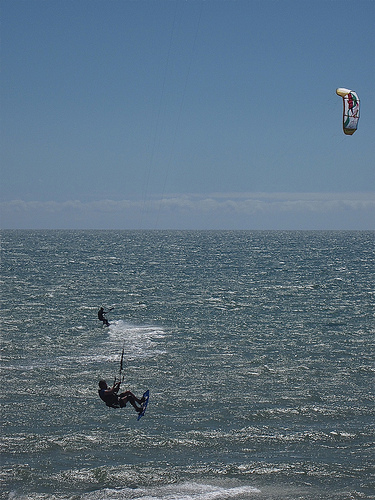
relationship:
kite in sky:
[335, 88, 360, 135] [0, 0, 373, 229]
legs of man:
[122, 390, 145, 412] [96, 377, 152, 422]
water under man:
[0, 229, 374, 499] [96, 377, 152, 422]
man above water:
[96, 377, 152, 422] [0, 229, 374, 499]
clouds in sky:
[2, 189, 374, 232] [0, 0, 373, 229]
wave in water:
[84, 481, 266, 500] [0, 229, 374, 499]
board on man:
[135, 389, 149, 421] [96, 377, 152, 422]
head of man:
[99, 379, 107, 388] [96, 377, 152, 422]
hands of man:
[114, 382, 121, 389] [96, 377, 152, 422]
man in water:
[96, 305, 116, 328] [0, 229, 374, 499]